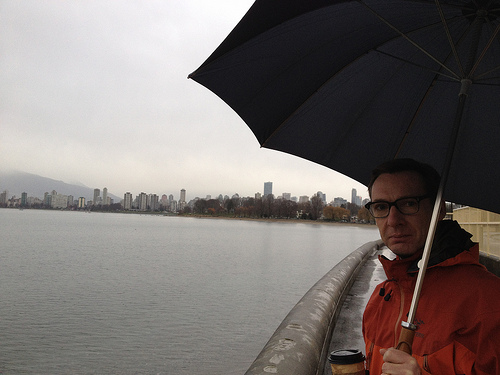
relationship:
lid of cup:
[329, 348, 356, 363] [315, 332, 357, 372]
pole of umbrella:
[407, 288, 422, 309] [209, 8, 459, 120]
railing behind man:
[276, 321, 313, 355] [346, 141, 478, 374]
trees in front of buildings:
[202, 200, 246, 218] [0, 175, 190, 218]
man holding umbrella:
[346, 141, 478, 374] [209, 8, 459, 120]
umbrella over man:
[209, 8, 459, 120] [346, 141, 478, 374]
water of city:
[84, 264, 137, 290] [129, 109, 308, 292]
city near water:
[129, 109, 308, 292] [84, 264, 137, 290]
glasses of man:
[351, 192, 418, 214] [346, 141, 478, 374]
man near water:
[346, 141, 478, 374] [84, 264, 137, 290]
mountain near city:
[2, 164, 75, 192] [129, 109, 308, 292]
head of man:
[355, 154, 439, 264] [346, 141, 478, 374]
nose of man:
[385, 215, 406, 228] [346, 141, 478, 374]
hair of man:
[395, 160, 416, 172] [346, 141, 478, 374]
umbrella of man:
[209, 8, 459, 120] [346, 141, 478, 374]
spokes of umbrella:
[411, 25, 486, 83] [209, 8, 459, 120]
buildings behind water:
[0, 175, 190, 218] [84, 264, 137, 290]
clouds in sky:
[97, 90, 128, 102] [111, 0, 139, 38]